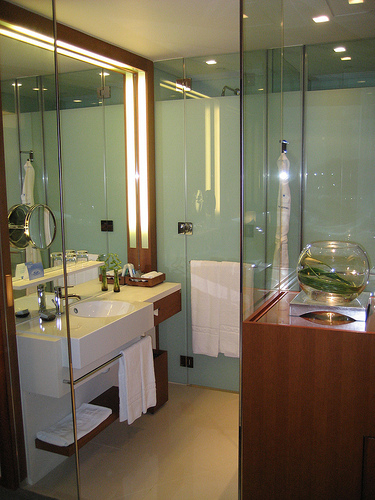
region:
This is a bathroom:
[33, 206, 268, 440]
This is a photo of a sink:
[51, 282, 139, 340]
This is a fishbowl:
[318, 228, 364, 348]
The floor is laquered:
[124, 424, 249, 498]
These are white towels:
[167, 267, 288, 366]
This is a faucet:
[28, 297, 78, 301]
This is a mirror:
[30, 160, 94, 225]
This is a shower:
[269, 176, 318, 221]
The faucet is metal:
[20, 283, 114, 331]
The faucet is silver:
[13, 282, 101, 308]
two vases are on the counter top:
[96, 251, 122, 292]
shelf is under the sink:
[36, 377, 153, 437]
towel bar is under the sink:
[64, 331, 154, 386]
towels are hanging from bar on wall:
[189, 260, 247, 358]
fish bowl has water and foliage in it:
[295, 238, 372, 310]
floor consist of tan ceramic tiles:
[33, 400, 233, 488]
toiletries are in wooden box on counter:
[98, 263, 166, 290]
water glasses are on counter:
[51, 249, 91, 285]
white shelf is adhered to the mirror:
[10, 260, 101, 292]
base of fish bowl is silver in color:
[289, 287, 372, 325]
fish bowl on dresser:
[297, 237, 370, 308]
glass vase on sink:
[112, 266, 123, 291]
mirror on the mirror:
[25, 205, 58, 249]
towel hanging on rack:
[118, 338, 156, 422]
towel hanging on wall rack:
[192, 258, 240, 360]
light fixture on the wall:
[123, 73, 159, 261]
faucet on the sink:
[55, 283, 79, 321]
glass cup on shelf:
[78, 250, 87, 266]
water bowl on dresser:
[295, 240, 367, 308]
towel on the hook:
[277, 138, 288, 291]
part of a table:
[322, 397, 341, 416]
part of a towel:
[140, 370, 154, 390]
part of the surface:
[190, 405, 201, 428]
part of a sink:
[97, 324, 109, 340]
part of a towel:
[216, 336, 221, 343]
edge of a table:
[265, 323, 271, 329]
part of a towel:
[87, 420, 104, 431]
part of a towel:
[217, 341, 225, 356]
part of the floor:
[229, 428, 235, 444]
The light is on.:
[6, 17, 153, 256]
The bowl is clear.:
[291, 233, 363, 313]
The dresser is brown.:
[233, 290, 372, 496]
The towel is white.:
[109, 345, 165, 413]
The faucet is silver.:
[42, 282, 87, 315]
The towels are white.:
[189, 254, 234, 361]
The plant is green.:
[97, 250, 123, 296]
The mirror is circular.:
[12, 202, 68, 252]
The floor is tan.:
[73, 387, 243, 497]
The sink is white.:
[61, 291, 127, 332]